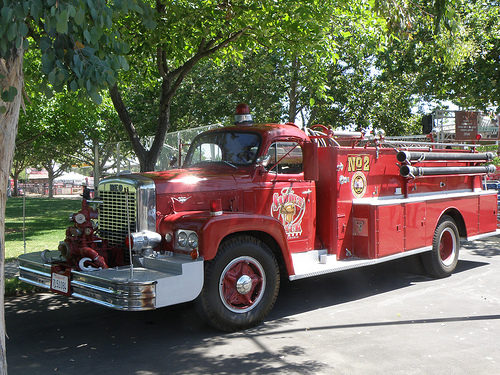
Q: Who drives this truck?
A: A fireman.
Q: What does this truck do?
A: Puts out fires.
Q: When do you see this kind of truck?
A: When theres a fire.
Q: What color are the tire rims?
A: Red.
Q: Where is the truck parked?
A: On the street.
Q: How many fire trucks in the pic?
A: 1.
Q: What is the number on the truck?
A: No. 2.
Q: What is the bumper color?
A: Chrome.